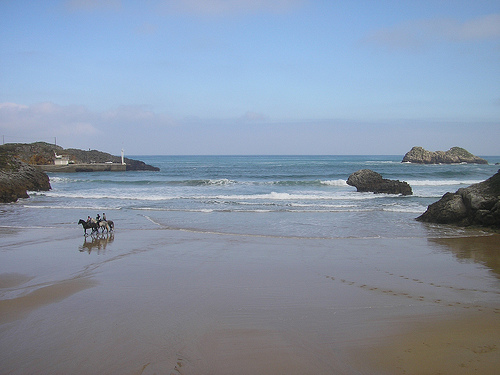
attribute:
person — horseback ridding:
[101, 213, 107, 223]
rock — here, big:
[419, 171, 499, 230]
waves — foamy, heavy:
[21, 176, 483, 212]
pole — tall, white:
[119, 149, 125, 166]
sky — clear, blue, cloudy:
[0, 0, 499, 155]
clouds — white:
[1, 104, 499, 155]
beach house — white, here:
[53, 155, 71, 165]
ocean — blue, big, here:
[41, 157, 498, 197]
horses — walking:
[79, 213, 115, 236]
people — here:
[86, 213, 107, 224]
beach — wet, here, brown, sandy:
[1, 225, 499, 372]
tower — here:
[54, 136, 59, 146]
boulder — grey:
[345, 167, 410, 195]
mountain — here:
[1, 142, 160, 172]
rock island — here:
[401, 146, 488, 165]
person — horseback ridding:
[85, 215, 94, 227]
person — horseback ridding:
[95, 214, 101, 223]